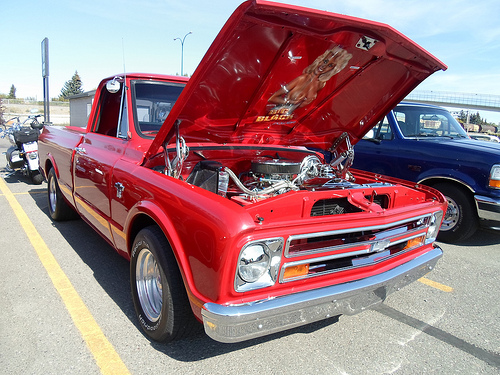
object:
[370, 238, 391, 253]
logo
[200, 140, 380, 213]
engine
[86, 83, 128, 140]
window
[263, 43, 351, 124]
woman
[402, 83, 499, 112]
overpass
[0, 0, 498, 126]
sky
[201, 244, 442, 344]
bumper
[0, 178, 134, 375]
line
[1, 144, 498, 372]
lot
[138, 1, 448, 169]
hood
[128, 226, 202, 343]
tire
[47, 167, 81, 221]
tire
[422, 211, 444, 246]
headlight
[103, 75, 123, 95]
mirror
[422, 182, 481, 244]
wheel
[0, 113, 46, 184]
motorcycle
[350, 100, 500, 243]
car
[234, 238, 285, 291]
headlight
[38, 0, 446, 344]
car